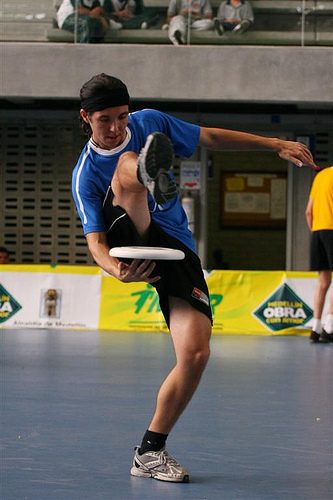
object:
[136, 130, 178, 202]
shoe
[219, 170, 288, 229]
bulletin board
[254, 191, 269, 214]
paper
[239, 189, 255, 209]
paper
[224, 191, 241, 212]
paper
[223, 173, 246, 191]
paper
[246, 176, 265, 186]
paper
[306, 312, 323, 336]
sock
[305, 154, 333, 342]
man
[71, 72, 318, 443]
man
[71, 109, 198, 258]
shirt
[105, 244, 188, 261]
frisbee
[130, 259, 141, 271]
fingertips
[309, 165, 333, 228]
t-shirt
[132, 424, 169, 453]
sock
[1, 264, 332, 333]
fencing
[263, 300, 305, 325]
name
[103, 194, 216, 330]
black shorts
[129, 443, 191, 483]
shoe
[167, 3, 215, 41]
spectator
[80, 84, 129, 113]
headband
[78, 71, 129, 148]
head